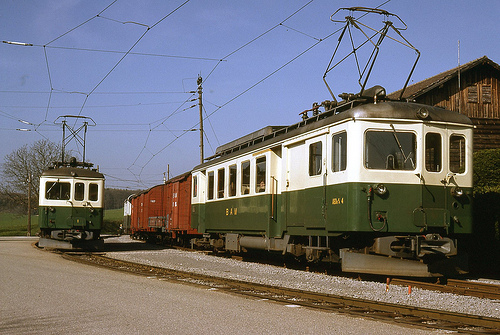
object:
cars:
[189, 85, 474, 277]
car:
[129, 172, 200, 249]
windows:
[253, 156, 268, 193]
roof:
[386, 58, 480, 99]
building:
[386, 56, 499, 151]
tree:
[3, 141, 81, 237]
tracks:
[261, 283, 498, 334]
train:
[124, 85, 472, 279]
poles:
[197, 73, 206, 163]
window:
[43, 180, 72, 201]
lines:
[76, 26, 153, 127]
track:
[391, 273, 499, 299]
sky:
[145, 25, 247, 117]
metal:
[222, 227, 322, 264]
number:
[329, 195, 347, 205]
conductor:
[322, 11, 354, 104]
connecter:
[409, 232, 457, 263]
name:
[223, 204, 241, 216]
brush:
[3, 225, 38, 233]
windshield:
[363, 127, 416, 170]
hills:
[95, 196, 125, 223]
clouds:
[138, 126, 182, 178]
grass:
[7, 210, 22, 225]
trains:
[37, 159, 109, 251]